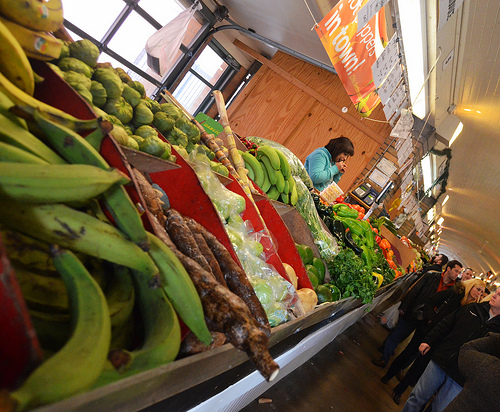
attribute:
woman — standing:
[275, 132, 373, 212]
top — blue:
[306, 147, 341, 192]